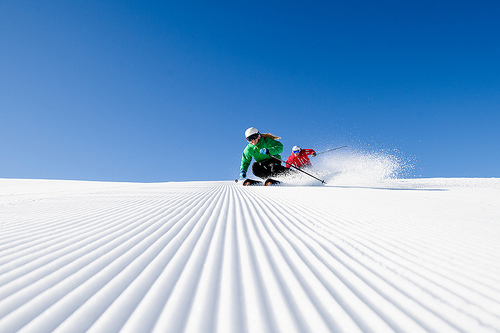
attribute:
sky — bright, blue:
[1, 0, 498, 126]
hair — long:
[259, 132, 280, 142]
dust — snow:
[326, 144, 434, 195]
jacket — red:
[286, 146, 318, 163]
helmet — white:
[290, 144, 300, 153]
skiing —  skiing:
[115, 87, 351, 202]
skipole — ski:
[255, 150, 327, 188]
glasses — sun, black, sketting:
[247, 132, 260, 140]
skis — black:
[237, 175, 284, 185]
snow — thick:
[47, 226, 348, 299]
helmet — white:
[244, 127, 260, 140]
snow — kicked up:
[247, 147, 402, 187]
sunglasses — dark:
[245, 130, 259, 141]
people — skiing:
[232, 124, 355, 192]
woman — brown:
[194, 82, 345, 222]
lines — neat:
[137, 215, 257, 308]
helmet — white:
[241, 120, 263, 140]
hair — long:
[246, 122, 276, 141]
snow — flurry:
[282, 147, 415, 189]